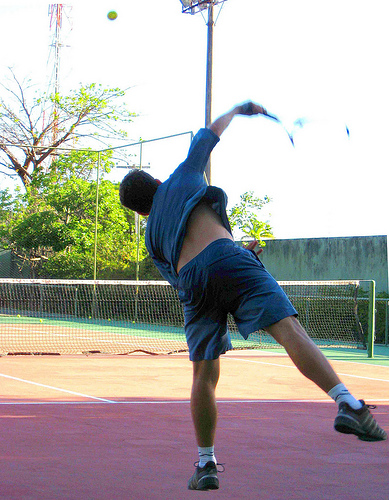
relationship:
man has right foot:
[119, 101, 386, 491] [332, 399, 387, 446]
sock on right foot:
[325, 383, 351, 404] [332, 399, 387, 446]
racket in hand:
[244, 101, 351, 156] [238, 102, 265, 118]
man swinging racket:
[90, 85, 376, 492] [242, 82, 371, 156]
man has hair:
[119, 101, 386, 491] [119, 167, 158, 212]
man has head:
[119, 101, 386, 491] [119, 169, 162, 217]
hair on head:
[119, 167, 158, 212] [119, 169, 162, 217]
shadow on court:
[46, 381, 322, 496] [29, 380, 386, 494]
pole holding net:
[351, 279, 381, 319] [9, 254, 380, 387]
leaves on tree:
[0, 63, 273, 278] [15, 182, 143, 277]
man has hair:
[119, 101, 386, 491] [118, 175, 157, 205]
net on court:
[58, 269, 134, 351] [0, 238, 386, 493]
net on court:
[1, 277, 367, 356] [0, 238, 386, 493]